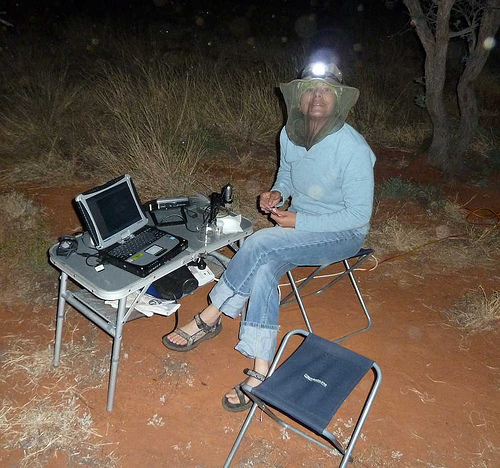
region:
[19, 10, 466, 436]
woman sitting outside with computer equipment.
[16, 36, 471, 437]
lady sitting outside with computer equipment.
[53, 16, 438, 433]
female sitting outside with computer equipment.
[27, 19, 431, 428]
person sitting outside with computer equipment.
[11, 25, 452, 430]
woman outside with computer equipment.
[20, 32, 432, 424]
lady outside with computer equipment.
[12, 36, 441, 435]
interesting lady outside with computer equipment.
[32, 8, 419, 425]
interesting person outside with computer equipment.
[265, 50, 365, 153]
person wearing head protection.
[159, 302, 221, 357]
sandal worn on foot.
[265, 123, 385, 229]
the woman is wearing a blue shirt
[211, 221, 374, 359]
the woman is wearing blue jeans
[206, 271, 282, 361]
the jeans have folded cuffs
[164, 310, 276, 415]
the woman is wearing sandals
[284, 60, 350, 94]
the woman is wearing a hat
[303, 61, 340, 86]
a headband light is on the hat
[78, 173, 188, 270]
a laptop is on the table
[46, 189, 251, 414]
the table is of the folding type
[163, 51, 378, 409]
the woman is in a sitting position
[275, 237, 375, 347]
the chair is of the folding type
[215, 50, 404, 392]
a woman sitting outside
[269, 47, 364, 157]
a lady with a bug net around her face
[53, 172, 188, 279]
laptop sitting on table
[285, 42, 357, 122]
woman with light on her head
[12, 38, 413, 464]
a woman outside at night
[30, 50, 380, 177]
dried out grass behind woman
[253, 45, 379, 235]
a woman in a blue sweater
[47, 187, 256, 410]
a small grey folding table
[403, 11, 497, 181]
a scary tree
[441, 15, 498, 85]
a white orb by a tree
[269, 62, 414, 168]
woman is wearing a bug netting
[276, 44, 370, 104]
the head light is on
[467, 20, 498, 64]
moon in the sky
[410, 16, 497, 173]
two trees in the background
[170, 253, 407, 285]
power line for the computer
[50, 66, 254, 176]
tall grass patches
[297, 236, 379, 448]
two blue foldable chairs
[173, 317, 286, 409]
woman is wearing sandals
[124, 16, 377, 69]
stars are in the sky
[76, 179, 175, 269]
laptop computer on a foldable table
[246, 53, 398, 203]
Woman wearing beekeeper mask.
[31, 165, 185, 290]
Laptop with protective shell.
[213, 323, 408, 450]
Small canvas and metal stool.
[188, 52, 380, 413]
Woman wearing velcro sandals.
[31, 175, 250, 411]
Small metal table with scientific gear.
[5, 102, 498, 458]
Small clearing in wilderness.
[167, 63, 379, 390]
Woman wearing rolled up jeans.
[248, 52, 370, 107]
Beekeeper's hat with flashlight.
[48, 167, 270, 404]
Laboratory equipment on a table.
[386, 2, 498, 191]
Small tree in a clearing.